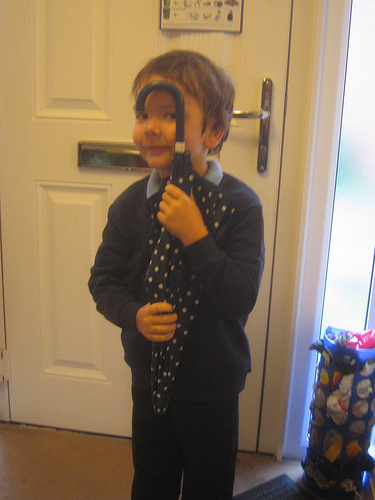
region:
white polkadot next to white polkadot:
[147, 275, 152, 282]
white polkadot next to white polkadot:
[156, 379, 159, 383]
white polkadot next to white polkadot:
[162, 371, 165, 376]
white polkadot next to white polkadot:
[152, 351, 157, 355]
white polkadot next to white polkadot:
[164, 345, 170, 350]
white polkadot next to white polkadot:
[179, 346, 182, 351]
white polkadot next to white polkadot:
[181, 307, 186, 313]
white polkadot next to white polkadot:
[188, 314, 192, 320]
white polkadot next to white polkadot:
[147, 276, 151, 281]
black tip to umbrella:
[137, 81, 185, 130]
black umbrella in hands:
[103, 184, 223, 425]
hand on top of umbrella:
[143, 295, 187, 345]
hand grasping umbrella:
[153, 188, 201, 230]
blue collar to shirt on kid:
[139, 177, 163, 204]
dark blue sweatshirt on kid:
[89, 189, 263, 358]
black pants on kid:
[118, 383, 249, 498]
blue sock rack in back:
[327, 326, 373, 491]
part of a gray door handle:
[222, 100, 264, 125]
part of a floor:
[1, 417, 135, 496]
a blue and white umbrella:
[129, 79, 239, 436]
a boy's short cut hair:
[127, 49, 236, 166]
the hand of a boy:
[154, 183, 204, 238]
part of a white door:
[1, 1, 279, 453]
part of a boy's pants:
[126, 391, 242, 499]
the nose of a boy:
[141, 115, 161, 136]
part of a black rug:
[235, 471, 309, 499]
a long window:
[321, 1, 373, 327]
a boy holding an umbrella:
[92, 48, 263, 494]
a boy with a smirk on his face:
[125, 45, 232, 170]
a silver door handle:
[229, 74, 275, 176]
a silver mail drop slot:
[78, 137, 144, 168]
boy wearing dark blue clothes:
[92, 47, 255, 497]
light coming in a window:
[306, 3, 373, 476]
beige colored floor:
[2, 423, 120, 498]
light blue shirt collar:
[138, 152, 226, 199]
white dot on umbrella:
[155, 390, 165, 403]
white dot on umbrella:
[170, 354, 180, 370]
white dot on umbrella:
[155, 350, 168, 364]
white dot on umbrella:
[147, 364, 156, 373]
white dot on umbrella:
[152, 405, 168, 414]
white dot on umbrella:
[170, 332, 182, 349]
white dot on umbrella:
[181, 328, 195, 343]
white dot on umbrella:
[172, 306, 192, 320]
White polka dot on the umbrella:
[186, 171, 194, 180]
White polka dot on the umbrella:
[173, 360, 179, 368]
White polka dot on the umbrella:
[170, 333, 178, 345]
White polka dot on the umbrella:
[185, 288, 193, 297]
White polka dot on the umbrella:
[146, 273, 154, 285]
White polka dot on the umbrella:
[164, 238, 171, 253]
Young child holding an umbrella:
[87, 46, 261, 498]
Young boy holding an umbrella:
[86, 49, 264, 499]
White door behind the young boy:
[0, 0, 296, 456]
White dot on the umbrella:
[158, 254, 164, 260]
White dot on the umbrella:
[164, 241, 170, 249]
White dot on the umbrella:
[147, 275, 153, 283]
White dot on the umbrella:
[153, 291, 158, 300]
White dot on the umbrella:
[155, 281, 164, 290]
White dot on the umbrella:
[179, 305, 187, 314]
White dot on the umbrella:
[181, 329, 187, 335]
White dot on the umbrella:
[171, 335, 177, 343]